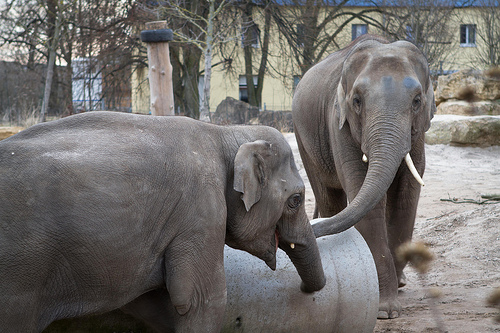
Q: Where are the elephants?
A: In a zoo.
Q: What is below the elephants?
A: A barrel.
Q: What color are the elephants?
A: Grey.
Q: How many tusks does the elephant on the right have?
A: One.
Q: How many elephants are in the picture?
A: Two.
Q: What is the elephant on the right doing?
A: Smelling the barrel.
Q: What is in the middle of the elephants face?
A: Trunks.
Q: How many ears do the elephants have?
A: Two.